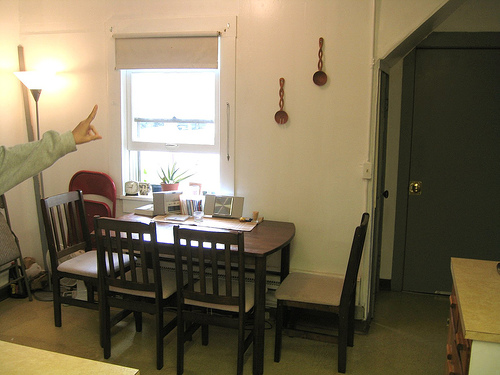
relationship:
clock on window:
[127, 177, 142, 196] [112, 35, 222, 189]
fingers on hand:
[72, 96, 102, 143] [73, 120, 93, 143]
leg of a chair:
[232, 317, 248, 373] [170, 222, 258, 370]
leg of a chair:
[100, 292, 112, 360] [92, 216, 182, 360]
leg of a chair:
[94, 292, 129, 360] [94, 214, 178, 351]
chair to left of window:
[70, 171, 114, 232] [110, 24, 232, 200]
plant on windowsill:
[153, 160, 191, 183] [119, 185, 216, 200]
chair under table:
[270, 205, 373, 373] [92, 198, 299, 344]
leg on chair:
[337, 317, 349, 373] [270, 205, 373, 373]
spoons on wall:
[262, 36, 334, 128] [299, 112, 350, 179]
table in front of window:
[110, 202, 296, 304] [114, 28, 236, 184]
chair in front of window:
[273, 212, 369, 373] [114, 28, 236, 184]